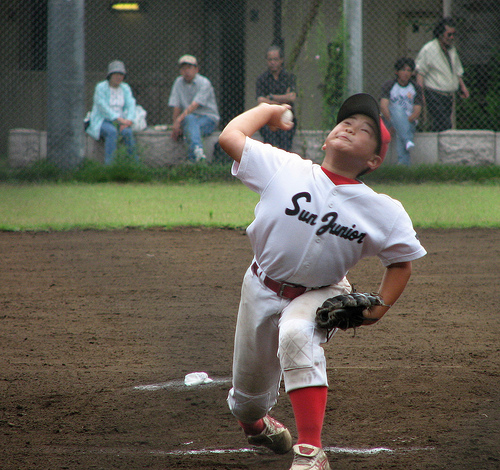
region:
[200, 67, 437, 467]
boy wearing a cap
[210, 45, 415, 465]
boy wearing a white shirt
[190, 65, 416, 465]
boy wearing white pants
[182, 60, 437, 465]
boy holding a glove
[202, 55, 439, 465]
boy wearing long socks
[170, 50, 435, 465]
boy throwing a ball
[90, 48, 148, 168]
woman wearing a hat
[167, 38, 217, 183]
man wearing a cap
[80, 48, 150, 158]
woman wearing blue jeans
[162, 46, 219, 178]
man wearing blue jeans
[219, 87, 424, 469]
child preparing to throw a baseball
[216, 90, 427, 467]
child wearing a baseball cap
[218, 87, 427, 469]
child with the word Sun Junior on his shirt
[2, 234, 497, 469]
dirt on the field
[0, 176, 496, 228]
grassy area behind the field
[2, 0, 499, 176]
fence separating the players from the spectators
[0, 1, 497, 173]
a chain link fence in front of the spectators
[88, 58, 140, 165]
woman wearing a gray hat and blue jeans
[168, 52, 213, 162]
man sitting on a concrete wall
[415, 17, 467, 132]
a dark haired man walking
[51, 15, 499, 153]
people sitting down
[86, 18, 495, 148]
people watching a baseball game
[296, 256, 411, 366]
a black baseball glove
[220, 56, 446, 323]
a small child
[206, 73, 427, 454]
a small boy playing baseball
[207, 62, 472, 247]
a small child holding a baseball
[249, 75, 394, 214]
a small boy wearing a hat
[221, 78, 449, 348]
a small boy holding a baseball glove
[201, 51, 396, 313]
a small boy wearing a belt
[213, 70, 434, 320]
a small boy wearing a white shirt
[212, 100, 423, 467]
the boy is trowind a ball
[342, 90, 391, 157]
the boy is wearing a cap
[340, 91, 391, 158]
the cap is red in color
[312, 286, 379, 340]
the boy is holding a baseball glove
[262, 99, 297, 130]
the boy is holding a ball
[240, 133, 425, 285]
the boy's shirt is short sleeve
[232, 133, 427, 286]
the shirt is white in color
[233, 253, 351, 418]
the pants are white in color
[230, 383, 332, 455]
the socks are red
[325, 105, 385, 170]
the boy has his head raised up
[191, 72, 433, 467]
boy throwing a baseball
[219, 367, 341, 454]
red baseball socks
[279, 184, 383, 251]
"Sun Junior" is written on his jersey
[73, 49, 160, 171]
woman wearing a blue jacket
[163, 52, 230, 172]
man wearing a hat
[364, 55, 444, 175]
man sitting with his legs crossed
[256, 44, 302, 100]
man wearing a black shirt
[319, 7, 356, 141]
vines growing on the fence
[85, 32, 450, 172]
four people sitting on a wall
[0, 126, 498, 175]
white stone wall